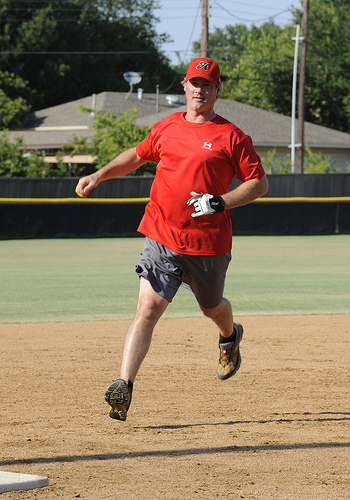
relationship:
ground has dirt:
[2, 233, 349, 500] [2, 313, 349, 499]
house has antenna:
[2, 93, 350, 178] [122, 69, 142, 97]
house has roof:
[2, 93, 350, 178] [4, 91, 350, 147]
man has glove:
[75, 57, 270, 421] [186, 189, 226, 218]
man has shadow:
[75, 57, 270, 421] [136, 410, 348, 429]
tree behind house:
[0, 0, 180, 110] [2, 93, 350, 178]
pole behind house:
[200, 2, 210, 58] [2, 93, 350, 178]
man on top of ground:
[75, 57, 270, 421] [2, 233, 349, 500]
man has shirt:
[75, 57, 270, 421] [135, 113, 264, 259]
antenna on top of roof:
[122, 69, 142, 97] [4, 91, 350, 147]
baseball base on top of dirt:
[1, 469, 47, 492] [2, 313, 349, 499]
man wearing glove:
[75, 57, 270, 421] [186, 189, 226, 218]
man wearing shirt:
[75, 57, 270, 421] [135, 113, 264, 259]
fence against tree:
[2, 176, 350, 235] [72, 101, 158, 176]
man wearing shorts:
[75, 57, 270, 421] [135, 238, 230, 309]